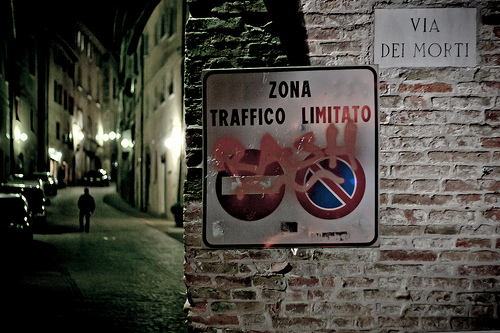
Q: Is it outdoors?
A: Yes, it is outdoors.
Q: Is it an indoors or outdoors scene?
A: It is outdoors.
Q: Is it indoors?
A: No, it is outdoors.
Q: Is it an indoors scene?
A: No, it is outdoors.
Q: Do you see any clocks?
A: No, there are no clocks.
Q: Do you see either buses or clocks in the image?
A: No, there are no clocks or buses.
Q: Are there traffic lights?
A: No, there are no traffic lights.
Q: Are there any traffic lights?
A: No, there are no traffic lights.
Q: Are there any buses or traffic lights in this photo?
A: No, there are no traffic lights or buses.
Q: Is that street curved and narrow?
A: Yes, the street is curved and narrow.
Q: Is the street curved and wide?
A: No, the street is curved but narrow.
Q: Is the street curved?
A: Yes, the street is curved.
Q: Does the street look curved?
A: Yes, the street is curved.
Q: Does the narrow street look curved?
A: Yes, the street is curved.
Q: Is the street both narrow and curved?
A: Yes, the street is narrow and curved.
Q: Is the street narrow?
A: Yes, the street is narrow.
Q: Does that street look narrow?
A: Yes, the street is narrow.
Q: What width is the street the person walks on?
A: The street is narrow.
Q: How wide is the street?
A: The street is narrow.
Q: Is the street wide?
A: No, the street is narrow.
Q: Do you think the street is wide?
A: No, the street is narrow.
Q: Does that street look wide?
A: No, the street is narrow.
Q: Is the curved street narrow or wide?
A: The street is narrow.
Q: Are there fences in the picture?
A: No, there are no fences.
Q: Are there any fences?
A: No, there are no fences.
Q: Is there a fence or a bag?
A: No, there are no fences or bags.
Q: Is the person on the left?
A: Yes, the person is on the left of the image.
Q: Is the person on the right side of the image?
A: No, the person is on the left of the image.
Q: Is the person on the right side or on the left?
A: The person is on the left of the image.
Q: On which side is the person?
A: The person is on the left of the image.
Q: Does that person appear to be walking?
A: Yes, the person is walking.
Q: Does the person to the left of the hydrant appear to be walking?
A: Yes, the person is walking.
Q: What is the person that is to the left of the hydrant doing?
A: The person is walking.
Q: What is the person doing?
A: The person is walking.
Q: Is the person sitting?
A: No, the person is walking.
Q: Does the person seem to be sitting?
A: No, the person is walking.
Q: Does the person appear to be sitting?
A: No, the person is walking.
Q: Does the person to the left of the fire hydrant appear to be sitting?
A: No, the person is walking.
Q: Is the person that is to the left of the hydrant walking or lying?
A: The person is walking.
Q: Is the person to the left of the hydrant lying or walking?
A: The person is walking.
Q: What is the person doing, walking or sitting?
A: The person is walking.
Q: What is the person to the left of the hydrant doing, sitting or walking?
A: The person is walking.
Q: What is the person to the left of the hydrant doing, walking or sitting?
A: The person is walking.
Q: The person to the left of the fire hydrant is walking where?
A: The person is walking on the street.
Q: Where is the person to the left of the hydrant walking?
A: The person is walking on the street.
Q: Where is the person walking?
A: The person is walking on the street.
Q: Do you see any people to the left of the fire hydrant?
A: Yes, there is a person to the left of the fire hydrant.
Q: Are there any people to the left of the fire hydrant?
A: Yes, there is a person to the left of the fire hydrant.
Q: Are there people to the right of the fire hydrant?
A: No, the person is to the left of the fire hydrant.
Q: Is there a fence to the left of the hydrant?
A: No, there is a person to the left of the hydrant.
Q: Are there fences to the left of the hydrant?
A: No, there is a person to the left of the hydrant.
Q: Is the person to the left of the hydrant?
A: Yes, the person is to the left of the hydrant.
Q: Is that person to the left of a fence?
A: No, the person is to the left of the hydrant.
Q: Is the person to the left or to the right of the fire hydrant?
A: The person is to the left of the fire hydrant.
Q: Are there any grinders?
A: No, there are no grinders.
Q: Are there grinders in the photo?
A: No, there are no grinders.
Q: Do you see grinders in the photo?
A: No, there are no grinders.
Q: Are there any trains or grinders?
A: No, there are no grinders or trains.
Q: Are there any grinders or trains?
A: No, there are no grinders or trains.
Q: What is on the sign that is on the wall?
A: The graffiti is on the traffic sign.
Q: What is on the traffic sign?
A: The graffiti is on the traffic sign.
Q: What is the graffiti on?
A: The graffiti is on the traffic sign.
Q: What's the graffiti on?
A: The graffiti is on the traffic sign.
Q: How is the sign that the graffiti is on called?
A: The sign is a traffic sign.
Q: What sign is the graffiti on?
A: The graffiti is on the traffic sign.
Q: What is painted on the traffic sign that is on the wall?
A: The graffiti is painted on the traffic sign.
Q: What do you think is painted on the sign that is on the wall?
A: The graffiti is painted on the traffic sign.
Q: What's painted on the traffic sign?
A: The graffiti is painted on the traffic sign.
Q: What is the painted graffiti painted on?
A: The graffiti is painted on the traffic sign.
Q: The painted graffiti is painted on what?
A: The graffiti is painted on the traffic sign.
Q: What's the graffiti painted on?
A: The graffiti is painted on the traffic sign.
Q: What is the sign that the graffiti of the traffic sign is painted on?
A: The sign is a traffic sign.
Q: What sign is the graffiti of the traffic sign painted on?
A: The graffiti is painted on the traffic sign.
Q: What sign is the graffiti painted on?
A: The graffiti is painted on the traffic sign.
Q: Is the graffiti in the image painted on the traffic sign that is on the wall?
A: Yes, the graffiti is painted on the traffic sign.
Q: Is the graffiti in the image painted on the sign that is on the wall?
A: Yes, the graffiti is painted on the traffic sign.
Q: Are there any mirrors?
A: No, there are no mirrors.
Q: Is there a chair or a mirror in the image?
A: No, there are no mirrors or chairs.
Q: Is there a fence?
A: No, there are no fences.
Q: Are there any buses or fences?
A: No, there are no fences or buses.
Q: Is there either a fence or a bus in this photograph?
A: No, there are no fences or buses.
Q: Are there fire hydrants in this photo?
A: Yes, there is a fire hydrant.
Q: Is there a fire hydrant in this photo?
A: Yes, there is a fire hydrant.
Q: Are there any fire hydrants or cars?
A: Yes, there is a fire hydrant.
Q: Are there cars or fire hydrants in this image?
A: Yes, there is a fire hydrant.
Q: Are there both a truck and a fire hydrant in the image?
A: No, there is a fire hydrant but no trucks.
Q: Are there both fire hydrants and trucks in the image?
A: No, there is a fire hydrant but no trucks.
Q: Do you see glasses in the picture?
A: No, there are no glasses.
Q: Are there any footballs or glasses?
A: No, there are no glasses or footballs.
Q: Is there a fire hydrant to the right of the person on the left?
A: Yes, there is a fire hydrant to the right of the person.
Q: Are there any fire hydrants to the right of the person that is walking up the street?
A: Yes, there is a fire hydrant to the right of the person.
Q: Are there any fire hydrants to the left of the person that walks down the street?
A: No, the fire hydrant is to the right of the person.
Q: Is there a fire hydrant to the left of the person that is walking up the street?
A: No, the fire hydrant is to the right of the person.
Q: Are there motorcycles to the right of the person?
A: No, there is a fire hydrant to the right of the person.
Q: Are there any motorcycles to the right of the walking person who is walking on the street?
A: No, there is a fire hydrant to the right of the person.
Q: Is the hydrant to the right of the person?
A: Yes, the hydrant is to the right of the person.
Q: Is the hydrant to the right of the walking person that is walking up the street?
A: Yes, the hydrant is to the right of the person.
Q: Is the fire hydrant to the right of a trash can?
A: No, the fire hydrant is to the right of the person.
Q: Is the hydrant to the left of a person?
A: No, the hydrant is to the right of a person.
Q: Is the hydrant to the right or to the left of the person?
A: The hydrant is to the right of the person.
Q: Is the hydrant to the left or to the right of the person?
A: The hydrant is to the right of the person.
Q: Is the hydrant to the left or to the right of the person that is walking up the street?
A: The hydrant is to the right of the person.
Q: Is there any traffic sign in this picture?
A: Yes, there is a traffic sign.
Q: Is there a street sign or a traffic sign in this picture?
A: Yes, there is a traffic sign.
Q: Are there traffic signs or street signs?
A: Yes, there is a traffic sign.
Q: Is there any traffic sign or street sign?
A: Yes, there is a traffic sign.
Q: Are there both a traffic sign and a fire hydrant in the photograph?
A: Yes, there are both a traffic sign and a fire hydrant.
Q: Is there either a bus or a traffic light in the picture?
A: No, there are no traffic lights or buses.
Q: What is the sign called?
A: The sign is a traffic sign.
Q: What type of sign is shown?
A: The sign is a traffic sign.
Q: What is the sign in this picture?
A: The sign is a traffic sign.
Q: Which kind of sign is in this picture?
A: The sign is a traffic sign.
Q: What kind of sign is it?
A: The sign is a traffic sign.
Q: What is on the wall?
A: The traffic sign is on the wall.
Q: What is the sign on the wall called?
A: The sign is a traffic sign.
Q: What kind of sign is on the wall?
A: The sign is a traffic sign.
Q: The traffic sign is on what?
A: The traffic sign is on the wall.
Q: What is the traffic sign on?
A: The traffic sign is on the wall.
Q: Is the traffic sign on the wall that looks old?
A: Yes, the traffic sign is on the wall.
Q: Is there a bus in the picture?
A: No, there are no buses.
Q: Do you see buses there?
A: No, there are no buses.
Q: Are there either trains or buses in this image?
A: No, there are no buses or trains.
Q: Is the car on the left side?
A: Yes, the car is on the left of the image.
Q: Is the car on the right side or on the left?
A: The car is on the left of the image.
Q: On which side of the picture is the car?
A: The car is on the left of the image.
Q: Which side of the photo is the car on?
A: The car is on the left of the image.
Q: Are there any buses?
A: No, there are no buses.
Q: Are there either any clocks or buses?
A: No, there are no buses or clocks.